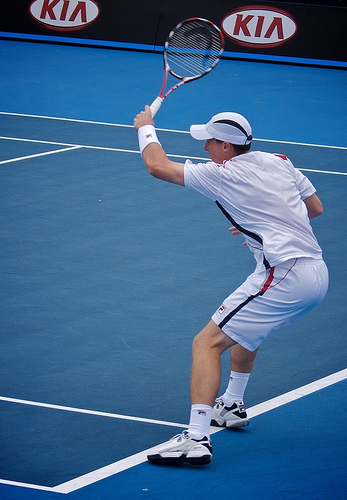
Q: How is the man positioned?
A: In a standing position.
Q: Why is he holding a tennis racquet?
A: To play tennis.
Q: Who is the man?
A: A tennis player.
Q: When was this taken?
A: During the daytime.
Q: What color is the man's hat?
A: Black and white.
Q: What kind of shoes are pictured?
A: Athletic shoes.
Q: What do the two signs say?
A: Kia.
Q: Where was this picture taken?
A: On a tennis court.